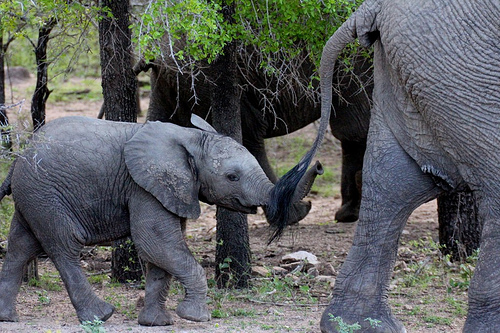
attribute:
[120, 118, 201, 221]
ear — large, gray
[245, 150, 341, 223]
elephant trunk — baby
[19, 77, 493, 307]
ground — sandy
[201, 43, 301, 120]
branches — some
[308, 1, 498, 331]
skin — wrinkled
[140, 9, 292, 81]
leaves — green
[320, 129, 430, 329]
leg — wrinkly, gray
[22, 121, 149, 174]
back — gray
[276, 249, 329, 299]
rocks — some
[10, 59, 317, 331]
elephant — walking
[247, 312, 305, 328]
sand — brown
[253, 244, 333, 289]
rocks — small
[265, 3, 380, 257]
tail — long, gray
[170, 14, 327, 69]
leaves — green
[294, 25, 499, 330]
elephant — wrinkly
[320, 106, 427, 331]
leg — gray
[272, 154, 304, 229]
hair — elephant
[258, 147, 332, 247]
hair — long